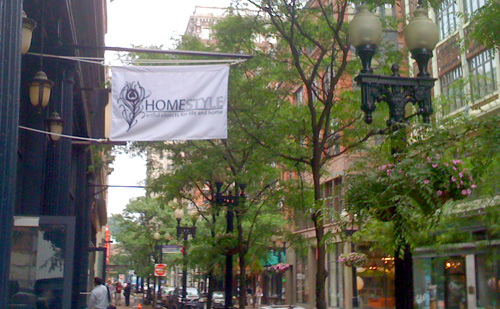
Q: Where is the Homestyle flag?
A: On a pole.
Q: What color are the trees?
A: Green.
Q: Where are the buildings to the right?
A: Behind the trees.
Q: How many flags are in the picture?
A: 1.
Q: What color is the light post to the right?
A: Black.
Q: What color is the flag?
A: White.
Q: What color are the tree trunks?
A: Brown.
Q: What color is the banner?
A: White.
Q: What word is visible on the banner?
A: Homestyle.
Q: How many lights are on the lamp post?
A: 2.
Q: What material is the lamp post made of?
A: Metal.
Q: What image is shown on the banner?
A: Peacock feather.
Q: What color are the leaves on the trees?
A: Green.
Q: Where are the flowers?
A: Hanging on the lamp post.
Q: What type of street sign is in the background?
A: Do Not Enter.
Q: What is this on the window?
A: Storefront.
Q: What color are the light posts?
A: Black.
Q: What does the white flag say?
A: Homestyle.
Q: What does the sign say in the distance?
A: Do not enter.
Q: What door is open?
A: The brown one on left.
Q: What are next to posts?
A: Trees.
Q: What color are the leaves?
A: Green.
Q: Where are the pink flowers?
A: Hanging from the lamp posts.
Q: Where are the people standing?
A: On the sidewalk.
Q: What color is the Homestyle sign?
A: White.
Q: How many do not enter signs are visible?
A: One.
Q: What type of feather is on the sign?
A: Peacock.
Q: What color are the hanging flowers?
A: Pink.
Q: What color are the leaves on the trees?
A: Green.